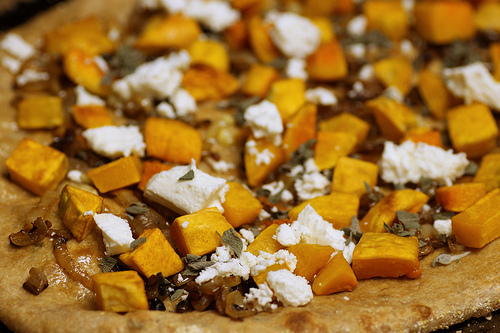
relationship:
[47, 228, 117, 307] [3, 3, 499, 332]
onion on pita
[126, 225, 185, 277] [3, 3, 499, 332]
potato on pita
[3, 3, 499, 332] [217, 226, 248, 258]
pita has spice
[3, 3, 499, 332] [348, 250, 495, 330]
pita has edge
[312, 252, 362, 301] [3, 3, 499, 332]
cheese on pita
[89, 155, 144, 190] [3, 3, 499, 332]
carrot on pita